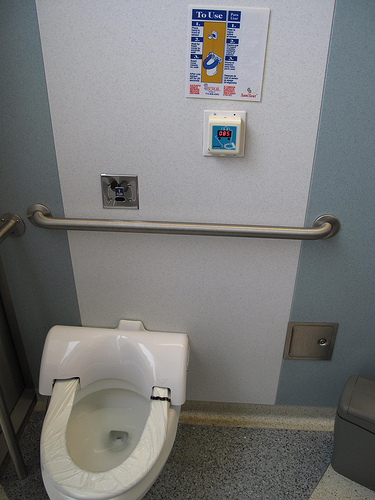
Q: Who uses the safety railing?
A: Handicapped people.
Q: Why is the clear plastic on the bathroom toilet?
A: Hygiene.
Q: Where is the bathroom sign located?
A: Above toilet.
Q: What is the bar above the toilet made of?
A: Metal.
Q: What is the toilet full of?
A: Water.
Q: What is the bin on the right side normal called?
A: Trashcan.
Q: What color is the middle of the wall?
A: White.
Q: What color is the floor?
A: Blue.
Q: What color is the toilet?
A: White.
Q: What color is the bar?
A: Gray.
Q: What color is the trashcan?
A: Gray.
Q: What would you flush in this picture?
A: Toilet.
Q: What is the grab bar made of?
A: Metal.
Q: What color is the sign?
A: White, Blue and Yellow.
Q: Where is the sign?
A: In the restroom.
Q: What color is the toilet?
A: White.